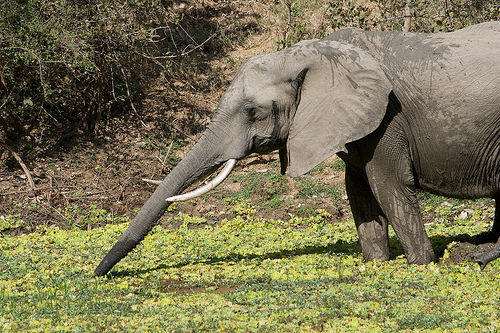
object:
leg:
[362, 124, 434, 253]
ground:
[0, 131, 499, 332]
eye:
[242, 106, 255, 114]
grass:
[1, 199, 500, 333]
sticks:
[1, 143, 120, 216]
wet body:
[350, 96, 487, 252]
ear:
[282, 44, 412, 180]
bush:
[0, 0, 225, 166]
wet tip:
[87, 234, 141, 279]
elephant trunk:
[95, 85, 249, 283]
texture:
[393, 119, 423, 179]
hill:
[0, 0, 499, 225]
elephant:
[80, 9, 499, 279]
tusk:
[139, 175, 165, 187]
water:
[4, 228, 496, 329]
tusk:
[166, 160, 236, 204]